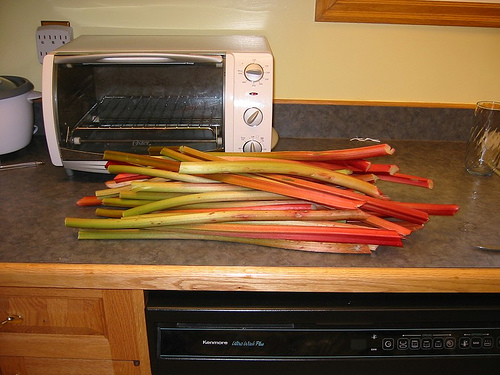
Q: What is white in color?
A: An oven.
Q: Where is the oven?
A: In the kitchen.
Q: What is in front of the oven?
A: Stalks.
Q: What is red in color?
A: The stalks.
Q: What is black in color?
A: The cooker.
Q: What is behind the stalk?
A: An oven.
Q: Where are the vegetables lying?
A: On the counter.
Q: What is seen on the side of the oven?
A: Three Knobs.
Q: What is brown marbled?
A: The counter.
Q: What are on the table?
A: Sticks.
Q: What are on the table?
A: Sticks.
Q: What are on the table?
A: Counter.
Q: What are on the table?
A: Counter.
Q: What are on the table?
A: Vegetables.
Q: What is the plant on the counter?
A: Rhubarb.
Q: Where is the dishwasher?
A: Under the counter.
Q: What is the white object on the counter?
A: Toaster oven.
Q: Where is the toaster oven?
A: On the counter.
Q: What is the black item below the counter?
A: Dishwasher.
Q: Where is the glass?
A: Far right.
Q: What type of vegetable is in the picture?
A: Rhubarb.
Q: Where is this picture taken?
A: In a kitchen.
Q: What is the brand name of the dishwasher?
A: Kenmore.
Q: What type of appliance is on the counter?
A: Toaster Oven.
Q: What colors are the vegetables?
A: Red and green.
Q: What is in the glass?
A: Nothing.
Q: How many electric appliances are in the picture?
A: Two.